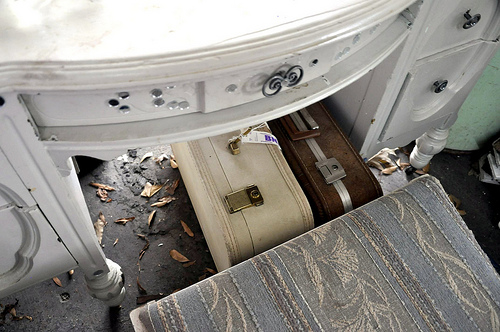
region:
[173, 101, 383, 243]
two suitcases sitting under the table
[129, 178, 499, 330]
the little bench to sit on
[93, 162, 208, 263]
pieces of wood on the floor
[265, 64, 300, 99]
the metal knob on the vanity table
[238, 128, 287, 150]
the tag on the suitcase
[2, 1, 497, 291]
the vanity table above the suitcases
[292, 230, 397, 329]
the flower pattern on the bench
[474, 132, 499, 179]
some blocks stacked together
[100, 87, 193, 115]
the dots on the desk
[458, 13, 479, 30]
the know of the drawer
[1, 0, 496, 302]
two suitcases under desk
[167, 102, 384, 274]
white suitcase left of brown suitcase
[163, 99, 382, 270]
brown suitcase right of white suitcase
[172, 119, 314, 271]
luggage tag on white suitcase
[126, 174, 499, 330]
blue and gray chair seat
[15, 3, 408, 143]
front drawer of white desk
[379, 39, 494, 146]
bottom right drawer of white desk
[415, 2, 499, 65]
top right drawer of white desk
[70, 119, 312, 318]
debris on floor left of white suitcase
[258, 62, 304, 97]
drawer pull of center drawer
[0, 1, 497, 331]
Interior view, daytime, with evidence of natural light.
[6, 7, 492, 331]
Bird's eye view of luggage and furniture with debris, suggesting autumn.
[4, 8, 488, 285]
Old-fashioned, feminine, white desk.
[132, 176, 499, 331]
Patterned, seat-cushion of chair.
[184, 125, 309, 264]
Hard-case white luggage, with metal fittings.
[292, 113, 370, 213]
Slender, brown, hard-cased luggage, with silver metal band and fittings.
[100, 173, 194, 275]
Black floor, without covering.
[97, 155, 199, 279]
Light and debris, suggesting nearby window with tree.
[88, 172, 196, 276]
Leafy bits on floor.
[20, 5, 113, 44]
Reflection on desk, suggesting window with blind and pull.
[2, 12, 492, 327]
two pieces of luggage on floor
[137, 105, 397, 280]
luggage partially under desk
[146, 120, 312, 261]
suitcase is khaki color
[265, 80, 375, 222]
dark brown suitcase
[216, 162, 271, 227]
suitcase has brass fixture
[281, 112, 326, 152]
suitcase has dark brown handle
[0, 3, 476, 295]
desk is painted white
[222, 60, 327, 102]
desk has silver fixture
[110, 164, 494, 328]
bench next to desk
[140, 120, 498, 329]
blue tapestry on bench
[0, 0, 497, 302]
White vanity table in the back.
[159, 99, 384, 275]
Luggage under the vanity.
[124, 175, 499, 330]
Vanity bench in the forefront.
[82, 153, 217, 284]
Brown leaves on the floor.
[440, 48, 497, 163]
Green wall in the background.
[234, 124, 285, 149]
White tag on the luggage bag.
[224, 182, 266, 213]
Lock on the suit case.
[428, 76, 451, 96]
round knob on the drawer.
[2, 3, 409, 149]
Drawer on the vanity.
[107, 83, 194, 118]
White padded stickers on drawer.